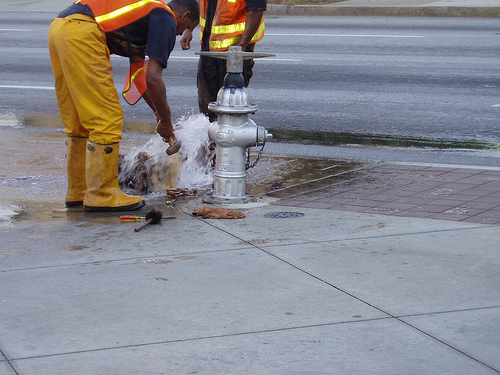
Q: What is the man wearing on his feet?
A: Galoshes.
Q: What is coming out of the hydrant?
A: Water.